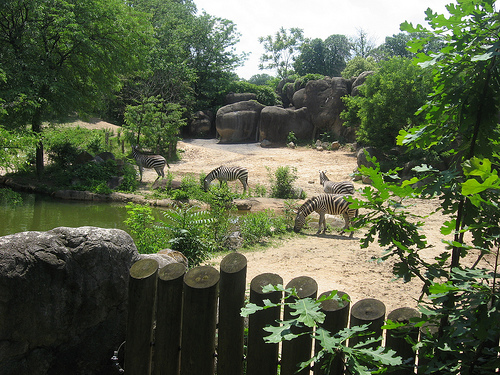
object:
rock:
[190, 70, 377, 148]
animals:
[125, 146, 360, 239]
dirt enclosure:
[45, 119, 500, 308]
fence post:
[312, 289, 351, 375]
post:
[214, 252, 248, 375]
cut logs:
[122, 247, 422, 375]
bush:
[264, 165, 308, 201]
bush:
[122, 201, 165, 255]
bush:
[239, 207, 286, 243]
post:
[343, 299, 382, 375]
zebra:
[294, 194, 359, 238]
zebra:
[318, 169, 354, 195]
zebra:
[202, 165, 251, 193]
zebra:
[131, 144, 170, 183]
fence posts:
[124, 249, 218, 375]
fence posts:
[179, 251, 282, 375]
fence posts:
[312, 289, 423, 375]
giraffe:
[131, 144, 171, 182]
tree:
[0, 0, 157, 179]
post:
[180, 264, 219, 374]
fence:
[125, 248, 453, 375]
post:
[152, 260, 187, 375]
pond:
[0, 182, 320, 238]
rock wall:
[186, 69, 376, 148]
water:
[0, 187, 333, 238]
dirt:
[0, 120, 500, 375]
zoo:
[0, 0, 500, 375]